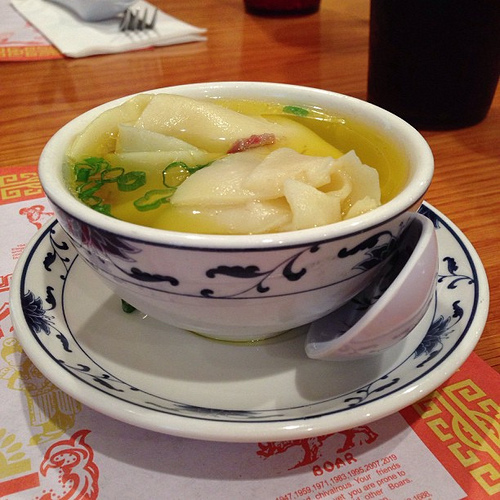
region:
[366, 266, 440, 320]
a spoon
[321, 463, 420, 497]
a placemat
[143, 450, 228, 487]
a shadow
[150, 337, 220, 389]
shadow on the plate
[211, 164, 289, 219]
food in the bowl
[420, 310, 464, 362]
design on the plate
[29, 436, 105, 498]
a red design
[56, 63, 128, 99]
the table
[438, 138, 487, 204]
a wooden table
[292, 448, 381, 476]
words on the place mat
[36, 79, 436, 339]
a soup in a white and blue bowl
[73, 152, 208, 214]
green onions in a soup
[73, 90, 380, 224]
won tons in a soup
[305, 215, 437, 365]
a small cup on a plate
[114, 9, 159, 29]
top of a stainless steel fork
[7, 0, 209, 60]
a white napkin on a table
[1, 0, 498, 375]
a wooden table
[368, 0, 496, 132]
a dark bottle on a wooden table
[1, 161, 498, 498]
a paper place mat on a table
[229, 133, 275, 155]
a bit of meat in a soup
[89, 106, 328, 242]
soup in a bowl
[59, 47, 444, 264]
soup in a bowl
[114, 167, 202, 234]
the soup is yellow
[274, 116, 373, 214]
the soup is yellow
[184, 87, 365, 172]
the soup is yellow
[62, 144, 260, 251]
the soup is yellow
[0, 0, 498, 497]
A restaurant table scene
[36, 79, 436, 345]
A bowl of soup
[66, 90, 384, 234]
Won-tons are in the soup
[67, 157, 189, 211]
Green onions are in the soup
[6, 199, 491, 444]
A saucer is under the bowl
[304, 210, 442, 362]
A spoon is on the saucer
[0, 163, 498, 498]
A place mat is on the table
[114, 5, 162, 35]
This is a fork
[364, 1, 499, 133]
A beverage glass is on the table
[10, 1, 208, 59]
A paper napkin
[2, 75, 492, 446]
Bowl of soup on a plate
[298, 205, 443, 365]
Soup spoon on a plate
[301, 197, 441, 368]
Soup spoon next to bowl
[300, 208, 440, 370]
Soup spoon next to bowl of soup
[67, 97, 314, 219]
Green onions in soup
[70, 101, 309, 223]
Sliced green onions in soup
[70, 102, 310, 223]
Scallions in soup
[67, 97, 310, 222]
Sliced scallions in soup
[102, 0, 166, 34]
Fork on a napkin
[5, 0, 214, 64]
Napkin on the table